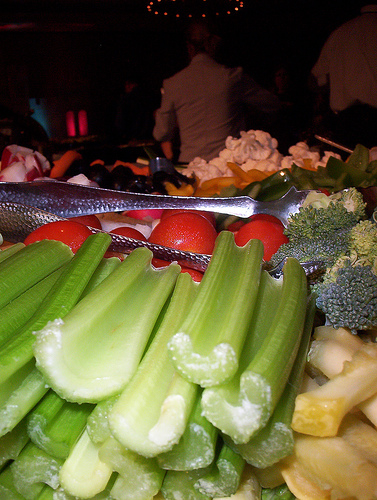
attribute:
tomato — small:
[148, 214, 219, 282]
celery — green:
[222, 293, 320, 468]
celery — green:
[0, 232, 113, 381]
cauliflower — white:
[221, 122, 278, 167]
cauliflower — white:
[286, 136, 324, 165]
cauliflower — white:
[183, 151, 237, 183]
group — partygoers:
[91, 1, 375, 166]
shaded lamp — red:
[59, 95, 137, 177]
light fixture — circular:
[147, 0, 243, 17]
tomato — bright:
[23, 207, 100, 254]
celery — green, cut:
[167, 230, 262, 388]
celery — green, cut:
[200, 257, 307, 443]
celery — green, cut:
[107, 269, 195, 458]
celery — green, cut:
[32, 245, 181, 403]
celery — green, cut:
[2, 232, 122, 435]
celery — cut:
[15, 248, 371, 490]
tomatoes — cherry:
[45, 211, 282, 251]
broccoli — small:
[276, 187, 376, 326]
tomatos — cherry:
[27, 205, 290, 274]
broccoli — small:
[320, 252, 362, 328]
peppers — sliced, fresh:
[214, 143, 376, 195]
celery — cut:
[1, 245, 305, 399]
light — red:
[46, 104, 105, 143]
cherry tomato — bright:
[155, 200, 250, 269]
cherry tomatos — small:
[66, 175, 277, 277]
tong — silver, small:
[1, 179, 327, 280]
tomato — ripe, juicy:
[148, 212, 215, 279]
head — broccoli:
[276, 190, 375, 329]